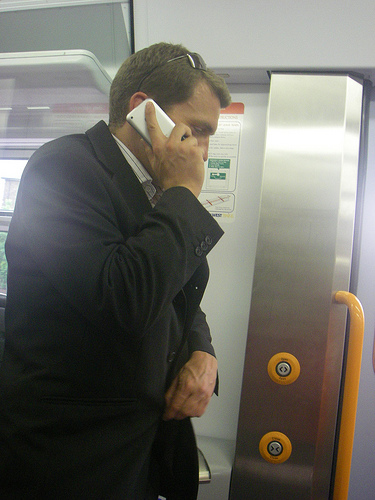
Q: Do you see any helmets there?
A: No, there are no helmets.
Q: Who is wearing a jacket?
A: The man is wearing a jacket.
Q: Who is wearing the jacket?
A: The man is wearing a jacket.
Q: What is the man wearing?
A: The man is wearing a jacket.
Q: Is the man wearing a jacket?
A: Yes, the man is wearing a jacket.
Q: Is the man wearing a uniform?
A: No, the man is wearing a jacket.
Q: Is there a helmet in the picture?
A: No, there are no helmets.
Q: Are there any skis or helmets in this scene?
A: No, there are no helmets or skis.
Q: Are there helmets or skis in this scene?
A: No, there are no helmets or skis.